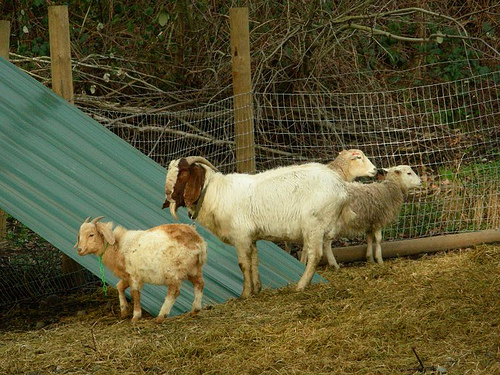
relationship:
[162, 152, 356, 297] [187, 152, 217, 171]
goat has horns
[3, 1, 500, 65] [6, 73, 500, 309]
shrubs behind fence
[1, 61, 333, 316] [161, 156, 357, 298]
metal sheeting by goat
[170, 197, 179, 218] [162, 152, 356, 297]
beard on goat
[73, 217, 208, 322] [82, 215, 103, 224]
baby goat has tiny horns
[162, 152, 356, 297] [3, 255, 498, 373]
goat on grass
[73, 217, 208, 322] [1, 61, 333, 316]
baby goat near metal sheeting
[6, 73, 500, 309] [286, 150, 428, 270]
fence next to sheep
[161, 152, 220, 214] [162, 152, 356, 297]
head of goat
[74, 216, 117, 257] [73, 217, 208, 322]
head of baby goat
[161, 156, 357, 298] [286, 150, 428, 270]
goat and sheep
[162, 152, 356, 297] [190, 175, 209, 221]
goat has a collar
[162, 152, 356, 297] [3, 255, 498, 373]
goat standing on grass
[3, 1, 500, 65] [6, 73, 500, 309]
shrubs behind a fence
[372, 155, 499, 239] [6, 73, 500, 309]
grass beyond fence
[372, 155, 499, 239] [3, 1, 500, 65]
grass below shrubs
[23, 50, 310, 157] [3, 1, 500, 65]
branches on shrubs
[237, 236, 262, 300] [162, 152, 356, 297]
front legs of goat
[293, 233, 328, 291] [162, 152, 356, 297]
back legs of goat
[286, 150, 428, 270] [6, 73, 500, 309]
sheep closer to fence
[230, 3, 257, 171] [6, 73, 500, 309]
pole for fence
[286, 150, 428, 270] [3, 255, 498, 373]
sheep on grass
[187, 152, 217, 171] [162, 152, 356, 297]
horns on goat